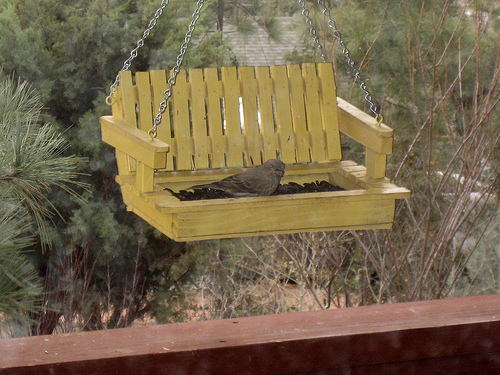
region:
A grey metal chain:
[151, 0, 209, 133]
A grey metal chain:
[108, 0, 168, 98]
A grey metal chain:
[295, 0, 327, 62]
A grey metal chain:
[318, 0, 383, 122]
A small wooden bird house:
[95, 50, 412, 247]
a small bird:
[181, 153, 292, 200]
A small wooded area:
[0, 0, 497, 337]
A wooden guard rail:
[1, 291, 498, 373]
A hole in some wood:
[229, 318, 242, 328]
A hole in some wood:
[217, 335, 227, 346]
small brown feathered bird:
[188, 152, 293, 203]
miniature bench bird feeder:
[98, 55, 417, 245]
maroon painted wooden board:
[1, 292, 494, 370]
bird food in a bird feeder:
[152, 170, 357, 205]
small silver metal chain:
[105, 0, 165, 100]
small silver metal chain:
[145, 0, 206, 140]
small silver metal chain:
[295, 0, 331, 65]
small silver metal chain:
[313, 0, 391, 131]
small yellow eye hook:
[146, 127, 154, 142]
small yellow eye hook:
[370, 112, 385, 127]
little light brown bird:
[186, 154, 288, 205]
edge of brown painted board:
[2, 295, 496, 374]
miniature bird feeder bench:
[94, 62, 413, 244]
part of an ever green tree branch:
[0, 68, 95, 333]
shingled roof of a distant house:
[210, 11, 323, 73]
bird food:
[162, 170, 352, 202]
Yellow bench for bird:
[95, 60, 417, 249]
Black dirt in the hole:
[162, 156, 354, 211]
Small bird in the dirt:
[187, 157, 288, 203]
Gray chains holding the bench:
[87, 0, 382, 152]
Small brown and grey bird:
[180, 133, 291, 208]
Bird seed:
[167, 169, 337, 219]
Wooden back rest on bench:
[120, 58, 341, 177]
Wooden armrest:
[334, 101, 394, 188]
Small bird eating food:
[183, 154, 293, 216]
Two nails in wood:
[217, 316, 242, 353]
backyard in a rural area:
[23, 10, 473, 357]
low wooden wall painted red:
[0, 290, 495, 370]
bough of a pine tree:
[0, 71, 70, 293]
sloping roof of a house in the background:
[225, 5, 305, 60]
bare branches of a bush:
[251, 235, 411, 301]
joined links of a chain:
[171, 0, 211, 65]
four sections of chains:
[125, 0, 365, 60]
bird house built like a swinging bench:
[101, 55, 406, 241]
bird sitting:
[185, 155, 285, 195]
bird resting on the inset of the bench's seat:
[151, 145, 366, 226]